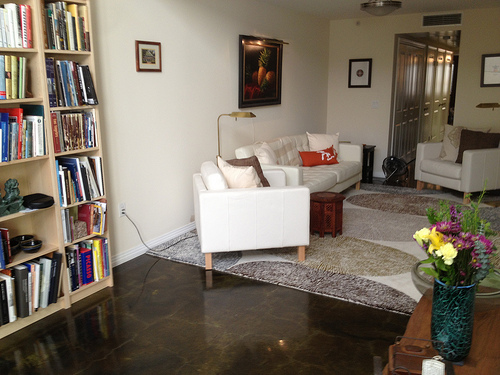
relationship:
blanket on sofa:
[266, 138, 301, 167] [234, 136, 362, 198]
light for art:
[261, 39, 290, 47] [237, 33, 284, 109]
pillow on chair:
[216, 157, 265, 190] [191, 169, 311, 269]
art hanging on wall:
[237, 33, 284, 109] [91, 0, 327, 266]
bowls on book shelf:
[13, 232, 43, 254] [0, 0, 115, 338]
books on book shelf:
[0, 2, 32, 47] [0, 0, 115, 338]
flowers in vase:
[409, 219, 494, 286] [431, 276, 476, 364]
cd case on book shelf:
[21, 192, 53, 212] [0, 0, 115, 338]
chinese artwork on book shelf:
[0, 178, 24, 215] [0, 0, 115, 338]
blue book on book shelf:
[2, 113, 9, 161] [0, 0, 115, 338]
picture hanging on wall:
[135, 40, 163, 74] [91, 0, 327, 266]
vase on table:
[431, 276, 476, 364] [384, 288, 499, 374]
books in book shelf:
[44, 1, 89, 51] [0, 0, 115, 338]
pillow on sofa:
[299, 149, 335, 166] [234, 136, 362, 198]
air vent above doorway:
[420, 14, 463, 26] [387, 31, 460, 179]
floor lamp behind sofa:
[217, 111, 253, 157] [234, 136, 362, 198]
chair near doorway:
[413, 126, 499, 203] [387, 31, 460, 179]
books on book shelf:
[0, 53, 35, 98] [0, 0, 115, 338]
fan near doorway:
[381, 154, 409, 186] [387, 31, 460, 179]